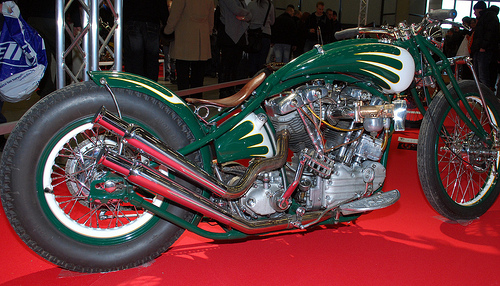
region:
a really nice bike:
[16, 14, 488, 284]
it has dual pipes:
[98, 115, 314, 245]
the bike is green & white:
[88, 33, 440, 171]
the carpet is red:
[256, 243, 461, 282]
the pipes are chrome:
[70, 93, 277, 244]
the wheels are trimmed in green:
[38, 103, 186, 281]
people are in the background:
[152, 4, 282, 68]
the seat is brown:
[174, 77, 273, 120]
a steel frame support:
[56, 5, 140, 72]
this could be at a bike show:
[0, 5, 494, 284]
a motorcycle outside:
[80, 18, 497, 251]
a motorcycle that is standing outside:
[58, 52, 490, 269]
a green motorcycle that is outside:
[17, 51, 479, 243]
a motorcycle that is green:
[78, 34, 433, 285]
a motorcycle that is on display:
[54, 61, 475, 285]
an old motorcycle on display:
[47, 44, 409, 251]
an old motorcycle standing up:
[60, 61, 488, 247]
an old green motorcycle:
[64, 55, 414, 283]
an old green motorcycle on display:
[32, 66, 410, 281]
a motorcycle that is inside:
[69, 52, 437, 277]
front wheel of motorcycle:
[411, 71, 498, 225]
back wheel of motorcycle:
[1, 70, 218, 279]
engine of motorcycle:
[277, 92, 407, 222]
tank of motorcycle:
[290, 35, 420, 93]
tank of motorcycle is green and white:
[290, 33, 416, 93]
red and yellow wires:
[285, 89, 352, 154]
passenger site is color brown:
[179, 65, 268, 115]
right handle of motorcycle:
[423, 5, 463, 25]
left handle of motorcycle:
[328, 20, 367, 38]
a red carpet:
[3, 123, 496, 280]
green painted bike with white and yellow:
[267, 37, 420, 92]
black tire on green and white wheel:
[3, 75, 202, 279]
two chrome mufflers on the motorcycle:
[91, 102, 338, 236]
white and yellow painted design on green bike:
[344, 37, 417, 97]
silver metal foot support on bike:
[333, 181, 406, 226]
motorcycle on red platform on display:
[11, 11, 496, 281]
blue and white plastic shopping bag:
[0, 9, 52, 101]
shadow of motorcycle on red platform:
[340, 215, 498, 279]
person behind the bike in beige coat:
[160, 0, 223, 103]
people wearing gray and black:
[217, 2, 276, 56]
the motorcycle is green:
[30, 7, 482, 248]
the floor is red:
[301, 237, 496, 275]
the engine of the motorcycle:
[277, 91, 367, 178]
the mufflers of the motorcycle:
[99, 108, 257, 223]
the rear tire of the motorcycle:
[9, 83, 193, 260]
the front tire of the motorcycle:
[426, 79, 498, 223]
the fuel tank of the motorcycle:
[290, 34, 415, 101]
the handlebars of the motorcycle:
[324, 2, 466, 49]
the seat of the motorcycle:
[155, 58, 283, 119]